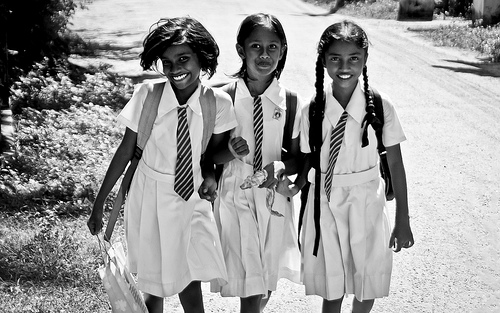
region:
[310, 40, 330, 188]
long braid in girl's hair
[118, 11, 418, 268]
school girls walking on the road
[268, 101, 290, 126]
small button shirt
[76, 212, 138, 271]
bag handle in girl's hand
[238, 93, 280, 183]
black and white stripe tie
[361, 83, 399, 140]
strap around girl's shoulders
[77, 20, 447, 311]
three friends posing for a photo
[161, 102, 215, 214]
a little girl's tie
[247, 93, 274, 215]
a little girl's tie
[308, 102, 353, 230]
a little girl's tie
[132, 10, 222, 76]
a little girl's short hair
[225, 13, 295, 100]
a little girl's straight hair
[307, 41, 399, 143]
a little girl's pigtails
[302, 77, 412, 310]
a little girl's white dress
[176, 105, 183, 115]
black stripe on tie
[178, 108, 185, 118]
black stripe on tie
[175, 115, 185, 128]
black stripe on tie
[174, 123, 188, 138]
black stripe on tie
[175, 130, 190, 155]
black stripe on tie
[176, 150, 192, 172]
black stripe on tie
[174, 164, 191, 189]
black stripe on tie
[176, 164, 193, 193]
black stripe on tie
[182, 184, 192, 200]
black stripe on tie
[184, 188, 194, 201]
black stripe on tie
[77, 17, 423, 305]
Three girls in a group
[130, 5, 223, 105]
The girl is facing the camera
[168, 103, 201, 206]
The girl has a striped tie on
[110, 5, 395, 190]
The girls are looking at the camera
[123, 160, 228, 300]
The girl is wearing a skirt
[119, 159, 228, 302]
The girl is wearing a white skirt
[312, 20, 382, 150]
The girl has ponytails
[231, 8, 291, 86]
The girl has her mouth closed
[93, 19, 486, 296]
three friends posing for a photo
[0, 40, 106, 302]
a patch of grass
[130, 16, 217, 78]
a short haircut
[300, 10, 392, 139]
a girl's pigtails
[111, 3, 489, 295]
a level stretch of road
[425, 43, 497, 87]
a tree's shadow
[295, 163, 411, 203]
a little girl's thick white belt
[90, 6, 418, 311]
three girls standing together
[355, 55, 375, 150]
a girl with long braids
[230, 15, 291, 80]
a girl with dark hair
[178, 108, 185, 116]
white stripe on tie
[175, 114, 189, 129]
white stripe on tie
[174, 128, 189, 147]
white stripe on tie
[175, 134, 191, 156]
white stripe on tie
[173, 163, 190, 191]
white stripe on tie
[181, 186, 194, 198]
white stripe on tie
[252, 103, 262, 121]
white stripe on tie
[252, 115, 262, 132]
white stripe on tie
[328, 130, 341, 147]
white stripe on tie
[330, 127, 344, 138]
white stripe on tie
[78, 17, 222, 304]
a person is standing up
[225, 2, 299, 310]
a person is standing up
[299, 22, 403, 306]
a person is standing up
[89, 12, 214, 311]
a person walking on a sidewalk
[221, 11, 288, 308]
a person walking on a street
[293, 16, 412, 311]
a person walking on a street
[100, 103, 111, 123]
a leaf on a stem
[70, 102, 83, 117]
a leaf on a stem